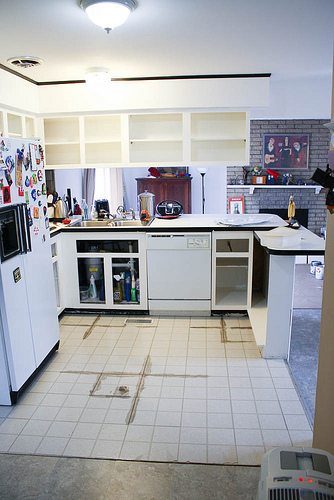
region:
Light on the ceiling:
[78, 4, 150, 47]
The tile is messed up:
[77, 337, 198, 431]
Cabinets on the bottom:
[75, 236, 154, 316]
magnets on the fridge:
[9, 135, 103, 250]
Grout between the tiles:
[184, 428, 227, 464]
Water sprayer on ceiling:
[9, 52, 44, 76]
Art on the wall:
[257, 128, 324, 185]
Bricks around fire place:
[280, 179, 302, 198]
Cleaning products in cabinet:
[102, 260, 162, 314]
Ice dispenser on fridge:
[0, 213, 31, 273]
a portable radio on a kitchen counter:
[156, 199, 183, 216]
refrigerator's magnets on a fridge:
[0, 140, 50, 241]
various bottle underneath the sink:
[88, 272, 141, 302]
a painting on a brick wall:
[263, 132, 310, 169]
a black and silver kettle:
[53, 195, 71, 221]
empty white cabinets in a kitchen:
[0, 110, 248, 164]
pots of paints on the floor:
[308, 261, 324, 279]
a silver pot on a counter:
[138, 188, 155, 219]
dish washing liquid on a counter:
[81, 197, 89, 220]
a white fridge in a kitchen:
[1, 135, 59, 395]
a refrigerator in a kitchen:
[4, 120, 91, 296]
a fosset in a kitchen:
[85, 197, 141, 237]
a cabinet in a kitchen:
[69, 246, 174, 321]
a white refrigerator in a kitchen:
[8, 124, 89, 294]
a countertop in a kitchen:
[134, 183, 308, 298]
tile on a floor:
[77, 336, 200, 429]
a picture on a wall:
[233, 126, 327, 189]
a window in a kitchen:
[75, 141, 202, 222]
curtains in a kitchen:
[70, 161, 155, 232]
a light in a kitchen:
[74, 10, 132, 42]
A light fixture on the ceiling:
[74, 0, 142, 37]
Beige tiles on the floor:
[1, 313, 313, 468]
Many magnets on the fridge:
[0, 138, 51, 285]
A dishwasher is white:
[141, 227, 214, 320]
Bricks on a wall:
[227, 120, 331, 237]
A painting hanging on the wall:
[259, 128, 312, 171]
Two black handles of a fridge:
[15, 200, 33, 255]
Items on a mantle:
[226, 165, 322, 195]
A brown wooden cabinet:
[134, 176, 193, 213]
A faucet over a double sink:
[66, 206, 140, 229]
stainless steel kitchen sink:
[68, 217, 154, 227]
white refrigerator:
[1, 138, 61, 394]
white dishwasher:
[146, 232, 215, 315]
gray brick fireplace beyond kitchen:
[229, 120, 326, 234]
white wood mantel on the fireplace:
[226, 182, 324, 194]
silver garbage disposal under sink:
[85, 246, 102, 281]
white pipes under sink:
[107, 243, 132, 276]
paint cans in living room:
[308, 260, 324, 278]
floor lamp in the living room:
[196, 169, 208, 213]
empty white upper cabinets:
[0, 113, 250, 167]